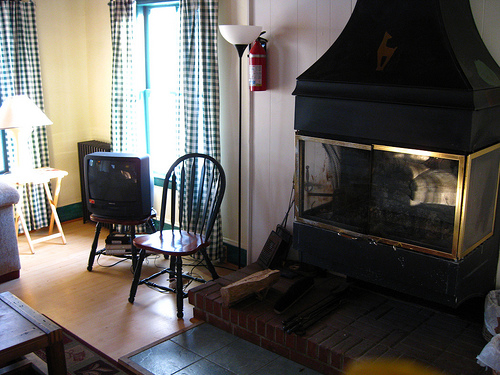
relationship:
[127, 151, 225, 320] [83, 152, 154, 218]
chair next to television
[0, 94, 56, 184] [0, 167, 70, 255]
lamp on top of folding table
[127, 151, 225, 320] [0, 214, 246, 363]
chair on floor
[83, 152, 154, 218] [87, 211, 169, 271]
television on stand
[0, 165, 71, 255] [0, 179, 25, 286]
end table by chair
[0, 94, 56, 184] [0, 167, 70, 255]
lamp on folding table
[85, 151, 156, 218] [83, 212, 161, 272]
television on stool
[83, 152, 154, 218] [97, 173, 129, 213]
television tv small